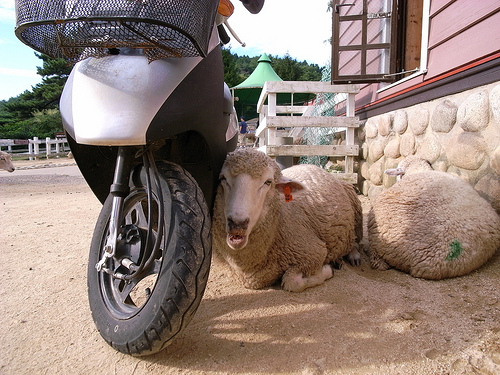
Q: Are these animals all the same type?
A: Yes, all the animals are sheep.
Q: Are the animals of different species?
A: No, all the animals are sheep.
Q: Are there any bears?
A: No, there are no bears.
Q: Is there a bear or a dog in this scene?
A: No, there are no bears or dogs.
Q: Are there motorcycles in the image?
A: Yes, there is a motorcycle.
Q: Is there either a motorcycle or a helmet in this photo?
A: Yes, there is a motorcycle.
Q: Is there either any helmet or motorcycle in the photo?
A: Yes, there is a motorcycle.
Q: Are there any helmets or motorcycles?
A: Yes, there is a motorcycle.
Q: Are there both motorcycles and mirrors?
A: No, there is a motorcycle but no mirrors.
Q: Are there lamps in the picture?
A: No, there are no lamps.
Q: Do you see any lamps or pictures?
A: No, there are no lamps or pictures.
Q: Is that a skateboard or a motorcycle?
A: That is a motorcycle.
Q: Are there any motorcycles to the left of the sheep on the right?
A: Yes, there is a motorcycle to the left of the sheep.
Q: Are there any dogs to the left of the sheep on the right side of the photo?
A: No, there is a motorcycle to the left of the sheep.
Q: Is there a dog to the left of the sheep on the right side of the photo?
A: No, there is a motorcycle to the left of the sheep.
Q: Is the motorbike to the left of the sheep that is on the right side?
A: Yes, the motorbike is to the left of the sheep.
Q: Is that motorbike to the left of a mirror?
A: No, the motorbike is to the left of the sheep.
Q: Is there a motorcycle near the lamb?
A: Yes, there is a motorcycle near the lamb.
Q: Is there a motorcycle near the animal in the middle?
A: Yes, there is a motorcycle near the lamb.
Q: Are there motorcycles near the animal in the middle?
A: Yes, there is a motorcycle near the lamb.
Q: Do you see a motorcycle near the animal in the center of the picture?
A: Yes, there is a motorcycle near the lamb.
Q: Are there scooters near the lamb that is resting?
A: No, there is a motorcycle near the lamb.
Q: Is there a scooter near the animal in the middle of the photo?
A: No, there is a motorcycle near the lamb.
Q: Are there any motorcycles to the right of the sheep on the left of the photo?
A: Yes, there is a motorcycle to the right of the sheep.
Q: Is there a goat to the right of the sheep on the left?
A: No, there is a motorcycle to the right of the sheep.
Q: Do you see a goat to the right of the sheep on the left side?
A: No, there is a motorcycle to the right of the sheep.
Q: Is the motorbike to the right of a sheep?
A: Yes, the motorbike is to the right of a sheep.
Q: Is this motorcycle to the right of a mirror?
A: No, the motorcycle is to the right of a sheep.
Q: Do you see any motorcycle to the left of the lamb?
A: Yes, there is a motorcycle to the left of the lamb.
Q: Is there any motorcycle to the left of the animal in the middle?
A: Yes, there is a motorcycle to the left of the lamb.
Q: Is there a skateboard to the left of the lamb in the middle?
A: No, there is a motorcycle to the left of the lamb.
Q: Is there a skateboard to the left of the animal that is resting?
A: No, there is a motorcycle to the left of the lamb.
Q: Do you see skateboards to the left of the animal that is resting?
A: No, there is a motorcycle to the left of the lamb.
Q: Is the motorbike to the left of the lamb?
A: Yes, the motorbike is to the left of the lamb.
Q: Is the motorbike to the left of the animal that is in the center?
A: Yes, the motorbike is to the left of the lamb.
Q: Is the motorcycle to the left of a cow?
A: No, the motorcycle is to the left of the lamb.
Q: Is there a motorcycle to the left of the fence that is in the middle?
A: Yes, there is a motorcycle to the left of the fence.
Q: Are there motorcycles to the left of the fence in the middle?
A: Yes, there is a motorcycle to the left of the fence.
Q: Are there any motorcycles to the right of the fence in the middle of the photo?
A: No, the motorcycle is to the left of the fence.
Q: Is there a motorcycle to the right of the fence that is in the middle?
A: No, the motorcycle is to the left of the fence.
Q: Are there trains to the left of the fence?
A: No, there is a motorcycle to the left of the fence.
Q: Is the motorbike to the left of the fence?
A: Yes, the motorbike is to the left of the fence.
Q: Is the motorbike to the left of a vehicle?
A: No, the motorbike is to the left of the fence.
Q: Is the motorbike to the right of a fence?
A: No, the motorbike is to the left of a fence.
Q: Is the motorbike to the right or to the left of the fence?
A: The motorbike is to the left of the fence.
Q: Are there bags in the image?
A: No, there are no bags.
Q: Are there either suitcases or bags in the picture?
A: No, there are no bags or suitcases.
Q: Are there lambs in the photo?
A: Yes, there is a lamb.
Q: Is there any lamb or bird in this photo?
A: Yes, there is a lamb.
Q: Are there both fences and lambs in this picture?
A: Yes, there are both a lamb and a fence.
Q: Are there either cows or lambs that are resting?
A: Yes, the lamb is resting.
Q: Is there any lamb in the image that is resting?
A: Yes, there is a lamb that is resting.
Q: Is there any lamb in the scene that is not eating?
A: Yes, there is a lamb that is resting.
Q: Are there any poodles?
A: No, there are no poodles.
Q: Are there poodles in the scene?
A: No, there are no poodles.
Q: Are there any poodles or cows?
A: No, there are no poodles or cows.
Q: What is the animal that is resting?
A: The animal is a lamb.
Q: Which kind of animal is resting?
A: The animal is a lamb.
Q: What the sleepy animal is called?
A: The animal is a lamb.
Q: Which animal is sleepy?
A: The animal is a lamb.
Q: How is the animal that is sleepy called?
A: The animal is a lamb.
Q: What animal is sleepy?
A: The animal is a lamb.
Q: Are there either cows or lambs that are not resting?
A: No, there is a lamb but it is resting.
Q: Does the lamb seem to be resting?
A: Yes, the lamb is resting.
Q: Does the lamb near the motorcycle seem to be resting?
A: Yes, the lamb is resting.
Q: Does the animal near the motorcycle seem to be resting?
A: Yes, the lamb is resting.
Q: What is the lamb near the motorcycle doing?
A: The lamb is resting.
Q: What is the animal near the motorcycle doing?
A: The lamb is resting.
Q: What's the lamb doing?
A: The lamb is resting.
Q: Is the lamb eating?
A: No, the lamb is resting.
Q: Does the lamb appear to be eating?
A: No, the lamb is resting.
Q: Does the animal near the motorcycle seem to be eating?
A: No, the lamb is resting.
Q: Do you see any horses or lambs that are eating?
A: No, there is a lamb but it is resting.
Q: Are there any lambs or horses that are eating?
A: No, there is a lamb but it is resting.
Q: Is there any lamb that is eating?
A: No, there is a lamb but it is resting.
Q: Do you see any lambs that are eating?
A: No, there is a lamb but it is resting.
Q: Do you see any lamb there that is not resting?
A: No, there is a lamb but it is resting.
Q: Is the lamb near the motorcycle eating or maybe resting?
A: The lamb is resting.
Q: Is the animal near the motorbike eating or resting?
A: The lamb is resting.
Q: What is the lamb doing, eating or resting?
A: The lamb is resting.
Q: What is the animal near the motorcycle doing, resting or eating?
A: The lamb is resting.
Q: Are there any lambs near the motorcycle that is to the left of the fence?
A: Yes, there is a lamb near the motorbike.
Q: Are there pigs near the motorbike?
A: No, there is a lamb near the motorbike.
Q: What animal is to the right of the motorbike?
A: The animal is a lamb.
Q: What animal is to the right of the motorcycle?
A: The animal is a lamb.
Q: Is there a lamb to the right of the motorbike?
A: Yes, there is a lamb to the right of the motorbike.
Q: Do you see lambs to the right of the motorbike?
A: Yes, there is a lamb to the right of the motorbike.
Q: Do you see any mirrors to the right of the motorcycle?
A: No, there is a lamb to the right of the motorcycle.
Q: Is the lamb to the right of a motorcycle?
A: Yes, the lamb is to the right of a motorcycle.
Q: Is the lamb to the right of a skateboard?
A: No, the lamb is to the right of a motorcycle.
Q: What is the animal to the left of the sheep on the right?
A: The animal is a lamb.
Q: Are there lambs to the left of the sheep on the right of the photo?
A: Yes, there is a lamb to the left of the sheep.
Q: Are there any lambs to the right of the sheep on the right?
A: No, the lamb is to the left of the sheep.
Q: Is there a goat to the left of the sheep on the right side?
A: No, there is a lamb to the left of the sheep.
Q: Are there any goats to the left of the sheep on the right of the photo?
A: No, there is a lamb to the left of the sheep.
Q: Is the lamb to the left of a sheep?
A: Yes, the lamb is to the left of a sheep.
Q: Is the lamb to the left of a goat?
A: No, the lamb is to the left of a sheep.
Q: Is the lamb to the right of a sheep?
A: No, the lamb is to the left of a sheep.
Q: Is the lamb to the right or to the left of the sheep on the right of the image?
A: The lamb is to the left of the sheep.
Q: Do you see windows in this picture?
A: Yes, there is a window.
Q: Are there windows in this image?
A: Yes, there is a window.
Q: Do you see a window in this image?
A: Yes, there is a window.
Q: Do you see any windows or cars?
A: Yes, there is a window.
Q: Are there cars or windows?
A: Yes, there is a window.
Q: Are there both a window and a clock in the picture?
A: No, there is a window but no clocks.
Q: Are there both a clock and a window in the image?
A: No, there is a window but no clocks.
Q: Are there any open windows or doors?
A: Yes, there is an open window.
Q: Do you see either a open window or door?
A: Yes, there is an open window.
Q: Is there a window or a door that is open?
A: Yes, the window is open.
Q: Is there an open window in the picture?
A: Yes, there is an open window.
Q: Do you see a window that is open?
A: Yes, there is a window that is open.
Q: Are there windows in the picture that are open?
A: Yes, there is a window that is open.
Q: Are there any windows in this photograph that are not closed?
A: Yes, there is a open window.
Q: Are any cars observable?
A: No, there are no cars.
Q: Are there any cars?
A: No, there are no cars.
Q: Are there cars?
A: No, there are no cars.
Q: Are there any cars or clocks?
A: No, there are no cars or clocks.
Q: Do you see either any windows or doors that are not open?
A: No, there is a window but it is open.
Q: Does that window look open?
A: Yes, the window is open.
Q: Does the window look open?
A: Yes, the window is open.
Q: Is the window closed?
A: No, the window is open.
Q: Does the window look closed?
A: No, the window is open.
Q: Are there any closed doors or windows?
A: No, there is a window but it is open.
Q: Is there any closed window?
A: No, there is a window but it is open.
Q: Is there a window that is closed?
A: No, there is a window but it is open.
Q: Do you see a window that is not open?
A: No, there is a window but it is open.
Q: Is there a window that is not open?
A: No, there is a window but it is open.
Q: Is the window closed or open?
A: The window is open.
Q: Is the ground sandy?
A: Yes, the ground is sandy.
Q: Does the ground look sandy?
A: Yes, the ground is sandy.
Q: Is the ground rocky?
A: No, the ground is sandy.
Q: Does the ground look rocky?
A: No, the ground is sandy.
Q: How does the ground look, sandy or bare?
A: The ground is sandy.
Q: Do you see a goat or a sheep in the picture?
A: Yes, there is a sheep.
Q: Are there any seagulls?
A: No, there are no seagulls.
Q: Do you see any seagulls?
A: No, there are no seagulls.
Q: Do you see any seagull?
A: No, there are no seagulls.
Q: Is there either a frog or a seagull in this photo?
A: No, there are no seagulls or frogs.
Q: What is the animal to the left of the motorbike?
A: The animal is a sheep.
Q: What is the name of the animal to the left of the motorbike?
A: The animal is a sheep.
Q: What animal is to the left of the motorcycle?
A: The animal is a sheep.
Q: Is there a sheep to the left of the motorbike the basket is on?
A: Yes, there is a sheep to the left of the motorbike.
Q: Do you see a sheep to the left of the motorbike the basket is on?
A: Yes, there is a sheep to the left of the motorbike.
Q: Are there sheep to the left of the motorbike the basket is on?
A: Yes, there is a sheep to the left of the motorbike.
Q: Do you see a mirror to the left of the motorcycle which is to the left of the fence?
A: No, there is a sheep to the left of the motorbike.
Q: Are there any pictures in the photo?
A: No, there are no pictures.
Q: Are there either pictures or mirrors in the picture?
A: No, there are no pictures or mirrors.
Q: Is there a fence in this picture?
A: Yes, there is a fence.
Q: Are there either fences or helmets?
A: Yes, there is a fence.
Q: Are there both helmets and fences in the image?
A: No, there is a fence but no helmets.